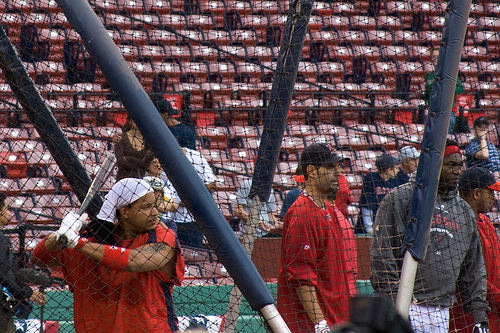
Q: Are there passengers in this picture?
A: No, there are no passengers.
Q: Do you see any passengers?
A: No, there are no passengers.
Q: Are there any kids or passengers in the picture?
A: No, there are no passengers or kids.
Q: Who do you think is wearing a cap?
A: The man is wearing a cap.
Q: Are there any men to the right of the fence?
A: Yes, there is a man to the right of the fence.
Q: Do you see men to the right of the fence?
A: Yes, there is a man to the right of the fence.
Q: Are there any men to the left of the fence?
A: No, the man is to the right of the fence.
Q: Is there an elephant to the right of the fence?
A: No, there is a man to the right of the fence.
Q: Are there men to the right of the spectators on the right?
A: Yes, there is a man to the right of the spectators.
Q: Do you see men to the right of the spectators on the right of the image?
A: Yes, there is a man to the right of the spectators.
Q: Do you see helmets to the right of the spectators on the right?
A: No, there is a man to the right of the spectators.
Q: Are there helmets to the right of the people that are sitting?
A: No, there is a man to the right of the spectators.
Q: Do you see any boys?
A: No, there are no boys.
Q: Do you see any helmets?
A: No, there are no helmets.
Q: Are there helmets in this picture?
A: No, there are no helmets.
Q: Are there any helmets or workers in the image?
A: No, there are no helmets or workers.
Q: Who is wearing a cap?
A: The man is wearing a cap.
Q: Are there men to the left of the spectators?
A: Yes, there is a man to the left of the spectators.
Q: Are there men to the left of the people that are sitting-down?
A: Yes, there is a man to the left of the spectators.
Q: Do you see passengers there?
A: No, there are no passengers.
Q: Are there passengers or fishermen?
A: No, there are no passengers or fishermen.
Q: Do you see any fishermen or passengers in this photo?
A: No, there are no passengers or fishermen.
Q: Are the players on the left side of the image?
A: Yes, the players are on the left of the image.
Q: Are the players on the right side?
A: No, the players are on the left of the image.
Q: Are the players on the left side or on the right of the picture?
A: The players are on the left of the image.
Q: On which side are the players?
A: The players are on the left of the image.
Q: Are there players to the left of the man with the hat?
A: Yes, there are players to the left of the man.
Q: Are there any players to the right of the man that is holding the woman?
A: No, the players are to the left of the man.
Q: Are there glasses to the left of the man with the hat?
A: No, there are players to the left of the man.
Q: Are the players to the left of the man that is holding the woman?
A: Yes, the players are to the left of the man.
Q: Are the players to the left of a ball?
A: No, the players are to the left of the man.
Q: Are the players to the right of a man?
A: No, the players are to the left of a man.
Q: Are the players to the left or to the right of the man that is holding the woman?
A: The players are to the left of the man.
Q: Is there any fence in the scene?
A: Yes, there is a fence.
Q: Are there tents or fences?
A: Yes, there is a fence.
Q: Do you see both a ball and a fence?
A: No, there is a fence but no balls.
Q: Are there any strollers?
A: No, there are no strollers.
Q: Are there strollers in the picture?
A: No, there are no strollers.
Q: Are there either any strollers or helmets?
A: No, there are no strollers or helmets.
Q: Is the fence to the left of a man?
A: Yes, the fence is to the left of a man.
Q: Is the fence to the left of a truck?
A: No, the fence is to the left of a man.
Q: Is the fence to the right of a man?
A: No, the fence is to the left of a man.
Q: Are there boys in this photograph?
A: No, there are no boys.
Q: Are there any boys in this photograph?
A: No, there are no boys.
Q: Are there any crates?
A: No, there are no crates.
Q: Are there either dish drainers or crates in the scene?
A: No, there are no crates or dish drainers.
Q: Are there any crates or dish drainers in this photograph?
A: No, there are no crates or dish drainers.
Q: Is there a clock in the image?
A: No, there are no clocks.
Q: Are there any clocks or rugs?
A: No, there are no clocks or rugs.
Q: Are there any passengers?
A: No, there are no passengers.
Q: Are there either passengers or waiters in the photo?
A: No, there are no passengers or waiters.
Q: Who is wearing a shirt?
A: The man is wearing a shirt.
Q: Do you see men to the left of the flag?
A: Yes, there is a man to the left of the flag.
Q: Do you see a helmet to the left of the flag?
A: No, there is a man to the left of the flag.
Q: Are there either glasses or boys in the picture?
A: No, there are no boys or glasses.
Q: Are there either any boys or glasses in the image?
A: No, there are no boys or glasses.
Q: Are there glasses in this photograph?
A: No, there are no glasses.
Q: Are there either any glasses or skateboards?
A: No, there are no glasses or skateboards.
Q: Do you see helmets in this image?
A: No, there are no helmets.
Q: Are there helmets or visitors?
A: No, there are no helmets or visitors.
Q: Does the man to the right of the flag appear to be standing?
A: Yes, the man is standing.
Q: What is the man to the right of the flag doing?
A: The man is standing.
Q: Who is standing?
A: The man is standing.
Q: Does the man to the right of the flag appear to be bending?
A: No, the man is standing.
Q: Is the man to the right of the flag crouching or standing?
A: The man is standing.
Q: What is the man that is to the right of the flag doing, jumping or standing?
A: The man is standing.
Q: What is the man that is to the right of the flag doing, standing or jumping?
A: The man is standing.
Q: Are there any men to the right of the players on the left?
A: Yes, there is a man to the right of the players.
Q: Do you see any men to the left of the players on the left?
A: No, the man is to the right of the players.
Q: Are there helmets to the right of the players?
A: No, there is a man to the right of the players.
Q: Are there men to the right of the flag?
A: Yes, there is a man to the right of the flag.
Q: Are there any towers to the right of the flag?
A: No, there is a man to the right of the flag.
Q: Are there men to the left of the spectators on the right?
A: Yes, there is a man to the left of the spectators.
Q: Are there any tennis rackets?
A: No, there are no tennis rackets.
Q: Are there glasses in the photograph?
A: No, there are no glasses.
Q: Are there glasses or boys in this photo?
A: No, there are no glasses or boys.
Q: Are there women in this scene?
A: Yes, there is a woman.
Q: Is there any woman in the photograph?
A: Yes, there is a woman.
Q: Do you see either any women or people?
A: Yes, there is a woman.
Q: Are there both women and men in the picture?
A: Yes, there are both a woman and a man.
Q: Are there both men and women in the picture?
A: Yes, there are both a woman and a man.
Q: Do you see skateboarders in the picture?
A: No, there are no skateboarders.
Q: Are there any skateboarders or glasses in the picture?
A: No, there are no skateboarders or glasses.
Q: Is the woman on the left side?
A: Yes, the woman is on the left of the image.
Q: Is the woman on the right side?
A: No, the woman is on the left of the image.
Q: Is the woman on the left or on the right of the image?
A: The woman is on the left of the image.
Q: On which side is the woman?
A: The woman is on the left of the image.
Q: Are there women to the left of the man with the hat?
A: Yes, there is a woman to the left of the man.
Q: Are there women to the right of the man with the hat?
A: No, the woman is to the left of the man.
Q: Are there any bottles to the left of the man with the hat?
A: No, there is a woman to the left of the man.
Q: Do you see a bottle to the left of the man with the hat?
A: No, there is a woman to the left of the man.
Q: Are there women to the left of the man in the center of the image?
A: Yes, there is a woman to the left of the man.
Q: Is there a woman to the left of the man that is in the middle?
A: Yes, there is a woman to the left of the man.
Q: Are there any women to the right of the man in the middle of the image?
A: No, the woman is to the left of the man.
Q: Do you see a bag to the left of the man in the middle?
A: No, there is a woman to the left of the man.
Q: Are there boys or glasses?
A: No, there are no boys or glasses.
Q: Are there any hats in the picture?
A: Yes, there is a hat.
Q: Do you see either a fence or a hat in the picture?
A: Yes, there is a hat.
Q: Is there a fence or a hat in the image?
A: Yes, there is a hat.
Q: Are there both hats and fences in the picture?
A: Yes, there are both a hat and a fence.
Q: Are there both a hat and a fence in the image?
A: Yes, there are both a hat and a fence.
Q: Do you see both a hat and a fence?
A: Yes, there are both a hat and a fence.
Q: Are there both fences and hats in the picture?
A: Yes, there are both a hat and a fence.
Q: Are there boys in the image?
A: No, there are no boys.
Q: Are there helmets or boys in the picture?
A: No, there are no boys or helmets.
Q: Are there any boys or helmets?
A: No, there are no boys or helmets.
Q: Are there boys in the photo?
A: No, there are no boys.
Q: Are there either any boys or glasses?
A: No, there are no boys or glasses.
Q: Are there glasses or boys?
A: No, there are no boys or glasses.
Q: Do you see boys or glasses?
A: No, there are no boys or glasses.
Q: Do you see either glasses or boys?
A: No, there are no boys or glasses.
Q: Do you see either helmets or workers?
A: No, there are no helmets or workers.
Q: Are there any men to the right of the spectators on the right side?
A: Yes, there is a man to the right of the spectators.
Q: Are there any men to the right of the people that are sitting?
A: Yes, there is a man to the right of the spectators.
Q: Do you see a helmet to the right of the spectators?
A: No, there is a man to the right of the spectators.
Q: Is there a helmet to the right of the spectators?
A: No, there is a man to the right of the spectators.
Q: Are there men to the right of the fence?
A: Yes, there is a man to the right of the fence.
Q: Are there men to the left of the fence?
A: No, the man is to the right of the fence.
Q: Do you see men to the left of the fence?
A: No, the man is to the right of the fence.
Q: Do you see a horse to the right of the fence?
A: No, there is a man to the right of the fence.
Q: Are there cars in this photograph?
A: No, there are no cars.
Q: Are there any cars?
A: No, there are no cars.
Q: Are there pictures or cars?
A: No, there are no cars or pictures.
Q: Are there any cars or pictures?
A: No, there are no cars or pictures.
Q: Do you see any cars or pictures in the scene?
A: No, there are no cars or pictures.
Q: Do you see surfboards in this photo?
A: No, there are no surfboards.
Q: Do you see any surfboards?
A: No, there are no surfboards.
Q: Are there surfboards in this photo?
A: No, there are no surfboards.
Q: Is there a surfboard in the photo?
A: No, there are no surfboards.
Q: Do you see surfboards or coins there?
A: No, there are no surfboards or coins.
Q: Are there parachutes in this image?
A: No, there are no parachutes.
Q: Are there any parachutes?
A: No, there are no parachutes.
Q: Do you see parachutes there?
A: No, there are no parachutes.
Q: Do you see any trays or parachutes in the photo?
A: No, there are no parachutes or trays.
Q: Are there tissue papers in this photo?
A: No, there are no tissue papers.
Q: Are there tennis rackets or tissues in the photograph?
A: No, there are no tissues or tennis rackets.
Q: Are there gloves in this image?
A: Yes, there are gloves.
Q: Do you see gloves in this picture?
A: Yes, there are gloves.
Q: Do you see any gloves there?
A: Yes, there are gloves.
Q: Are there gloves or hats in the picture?
A: Yes, there are gloves.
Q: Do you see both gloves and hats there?
A: Yes, there are both gloves and a hat.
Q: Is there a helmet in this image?
A: No, there are no helmets.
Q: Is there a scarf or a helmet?
A: No, there are no helmets or scarves.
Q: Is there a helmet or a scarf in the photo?
A: No, there are no helmets or scarves.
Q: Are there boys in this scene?
A: No, there are no boys.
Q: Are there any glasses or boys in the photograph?
A: No, there are no boys or glasses.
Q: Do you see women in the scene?
A: Yes, there is a woman.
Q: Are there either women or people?
A: Yes, there is a woman.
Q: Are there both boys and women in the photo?
A: No, there is a woman but no boys.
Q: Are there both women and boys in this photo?
A: No, there is a woman but no boys.